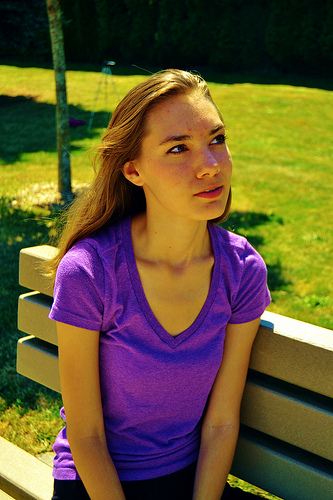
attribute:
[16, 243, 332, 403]
top of bench — white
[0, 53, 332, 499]
grass — brown, green, bright green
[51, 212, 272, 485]
tee shirt — purple, v neck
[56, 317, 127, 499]
arm — tanned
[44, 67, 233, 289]
hair — long, blond, brown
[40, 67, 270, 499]
girl — young, looking up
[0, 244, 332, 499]
bench — brown, to sit on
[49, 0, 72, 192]
trunk — of tree, skinny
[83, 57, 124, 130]
tripod — for camera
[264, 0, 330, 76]
tree — green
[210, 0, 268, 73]
tree — green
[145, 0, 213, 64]
tree — green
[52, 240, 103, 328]
sleeve — short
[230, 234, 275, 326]
sleeve — short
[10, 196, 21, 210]
flower — small